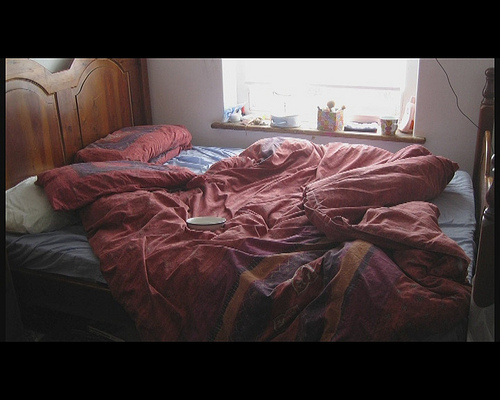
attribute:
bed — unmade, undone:
[11, 51, 492, 338]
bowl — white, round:
[183, 213, 231, 232]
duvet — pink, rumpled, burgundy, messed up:
[74, 138, 463, 341]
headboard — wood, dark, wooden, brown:
[0, 57, 157, 189]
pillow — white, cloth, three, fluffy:
[5, 170, 78, 240]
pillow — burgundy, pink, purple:
[75, 114, 193, 160]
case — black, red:
[77, 118, 194, 164]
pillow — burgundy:
[32, 158, 209, 214]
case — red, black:
[34, 153, 202, 214]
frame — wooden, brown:
[463, 66, 500, 308]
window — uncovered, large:
[214, 58, 423, 155]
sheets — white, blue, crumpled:
[3, 140, 479, 322]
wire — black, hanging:
[432, 60, 485, 138]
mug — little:
[380, 117, 399, 133]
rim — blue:
[186, 221, 227, 228]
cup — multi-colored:
[377, 116, 403, 141]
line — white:
[12, 264, 111, 291]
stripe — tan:
[123, 69, 137, 128]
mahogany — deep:
[6, 57, 157, 182]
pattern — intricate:
[8, 59, 140, 180]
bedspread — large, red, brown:
[52, 121, 473, 336]